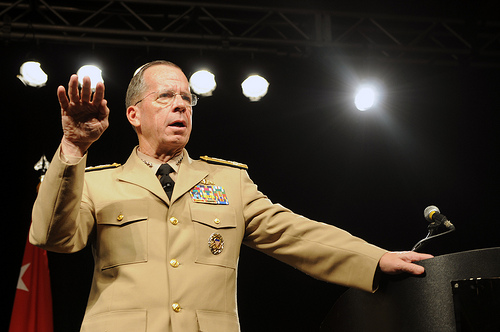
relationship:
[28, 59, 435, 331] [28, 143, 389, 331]
man in uniform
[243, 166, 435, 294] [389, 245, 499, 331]
arm on podium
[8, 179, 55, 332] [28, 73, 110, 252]
flag behind arm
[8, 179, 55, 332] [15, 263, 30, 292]
flag has design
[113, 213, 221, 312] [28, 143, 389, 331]
buttons on uniform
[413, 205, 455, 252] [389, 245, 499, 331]
microphone over podium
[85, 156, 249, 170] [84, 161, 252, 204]
epaulets on shoulders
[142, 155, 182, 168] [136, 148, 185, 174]
stars on collar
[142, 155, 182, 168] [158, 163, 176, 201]
stars above tie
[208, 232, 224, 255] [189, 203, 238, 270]
insignia on pocket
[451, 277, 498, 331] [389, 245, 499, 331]
speaker on podium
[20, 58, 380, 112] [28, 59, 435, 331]
lights behind man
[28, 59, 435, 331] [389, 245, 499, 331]
man next to podium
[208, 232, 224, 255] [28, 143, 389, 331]
insignia on uniform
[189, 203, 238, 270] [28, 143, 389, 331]
pocket on uniform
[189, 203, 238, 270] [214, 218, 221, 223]
pocket has button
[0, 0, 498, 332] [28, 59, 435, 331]
blackdrop behind man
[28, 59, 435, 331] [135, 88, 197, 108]
man has glasses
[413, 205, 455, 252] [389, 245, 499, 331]
microphone on podium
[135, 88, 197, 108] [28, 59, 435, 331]
glasses on man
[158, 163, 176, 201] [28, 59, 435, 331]
tie on man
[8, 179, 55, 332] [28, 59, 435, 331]
flag behind man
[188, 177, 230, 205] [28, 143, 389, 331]
medals on uniform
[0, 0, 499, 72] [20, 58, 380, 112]
railing above lights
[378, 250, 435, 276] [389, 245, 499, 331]
hand on podium